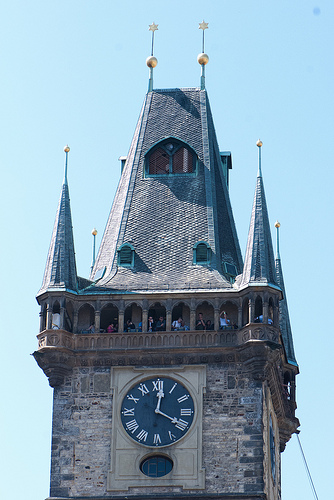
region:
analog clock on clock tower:
[119, 373, 195, 446]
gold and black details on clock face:
[119, 376, 194, 447]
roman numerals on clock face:
[121, 378, 193, 443]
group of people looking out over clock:
[80, 309, 272, 344]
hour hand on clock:
[155, 389, 164, 413]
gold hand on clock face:
[154, 408, 183, 425]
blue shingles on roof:
[36, 87, 297, 371]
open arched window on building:
[75, 302, 94, 333]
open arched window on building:
[98, 303, 119, 331]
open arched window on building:
[123, 302, 143, 331]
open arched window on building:
[147, 302, 166, 330]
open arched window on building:
[171, 302, 190, 329]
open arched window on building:
[195, 301, 214, 330]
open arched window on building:
[219, 301, 236, 329]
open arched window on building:
[241, 299, 249, 325]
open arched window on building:
[254, 293, 264, 322]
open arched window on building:
[268, 293, 276, 324]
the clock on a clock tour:
[113, 370, 198, 486]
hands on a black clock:
[150, 388, 182, 425]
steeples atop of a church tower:
[30, 9, 305, 441]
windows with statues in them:
[39, 293, 284, 346]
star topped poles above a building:
[137, 15, 217, 93]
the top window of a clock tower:
[140, 132, 205, 180]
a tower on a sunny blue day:
[1, 2, 332, 499]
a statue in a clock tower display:
[194, 308, 209, 327]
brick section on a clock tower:
[54, 367, 283, 497]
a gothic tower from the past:
[31, 15, 304, 496]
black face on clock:
[118, 374, 199, 448]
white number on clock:
[151, 375, 166, 393]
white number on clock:
[164, 378, 181, 394]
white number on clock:
[175, 394, 193, 404]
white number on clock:
[179, 407, 196, 418]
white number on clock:
[176, 417, 188, 434]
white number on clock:
[165, 431, 176, 443]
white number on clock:
[151, 431, 165, 445]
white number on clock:
[133, 429, 147, 443]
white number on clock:
[126, 414, 137, 434]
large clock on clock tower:
[114, 370, 199, 448]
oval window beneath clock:
[138, 450, 174, 478]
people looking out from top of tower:
[87, 305, 274, 335]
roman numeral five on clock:
[165, 427, 177, 442]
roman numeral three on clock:
[179, 405, 192, 416]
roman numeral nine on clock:
[119, 405, 135, 416]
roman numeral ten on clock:
[126, 392, 139, 404]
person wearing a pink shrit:
[103, 319, 115, 334]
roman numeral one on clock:
[167, 381, 178, 394]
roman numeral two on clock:
[176, 391, 188, 403]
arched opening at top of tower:
[50, 299, 62, 328]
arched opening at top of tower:
[64, 300, 74, 331]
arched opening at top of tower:
[76, 302, 96, 332]